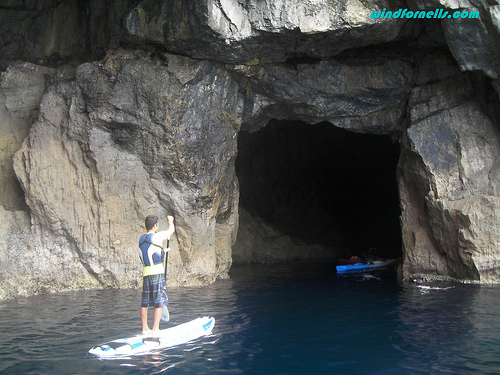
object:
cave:
[216, 94, 433, 298]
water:
[0, 264, 500, 374]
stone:
[175, 138, 232, 267]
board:
[88, 315, 216, 360]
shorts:
[139, 273, 169, 308]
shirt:
[139, 234, 168, 276]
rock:
[405, 133, 472, 247]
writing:
[370, 7, 484, 19]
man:
[139, 215, 176, 339]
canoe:
[337, 256, 391, 282]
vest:
[135, 233, 168, 278]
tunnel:
[232, 119, 385, 277]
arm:
[162, 213, 176, 241]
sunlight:
[23, 146, 112, 252]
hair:
[145, 215, 155, 229]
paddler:
[160, 219, 174, 323]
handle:
[166, 218, 173, 260]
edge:
[193, 311, 217, 337]